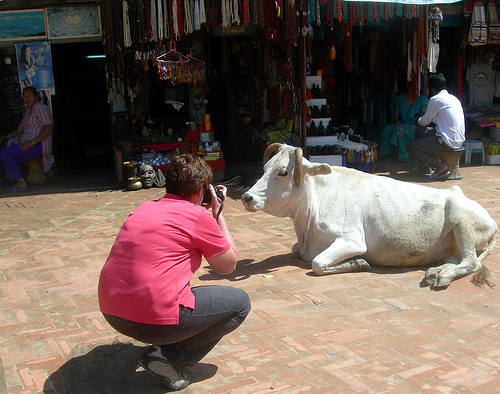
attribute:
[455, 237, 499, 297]
tail — cows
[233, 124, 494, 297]
cow — white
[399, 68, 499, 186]
person — sitting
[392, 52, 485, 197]
man — sitting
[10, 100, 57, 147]
shirt — striped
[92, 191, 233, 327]
shirt — red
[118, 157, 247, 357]
shirt — pink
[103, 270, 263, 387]
pants — purple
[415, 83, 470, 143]
shirt — white